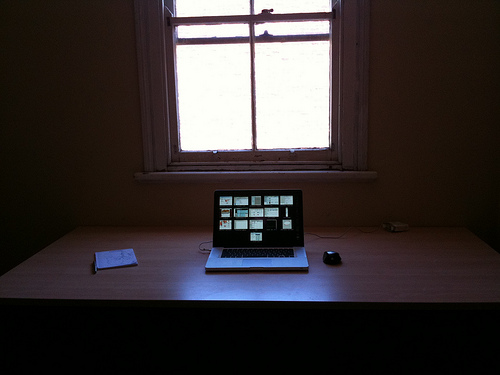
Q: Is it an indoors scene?
A: Yes, it is indoors.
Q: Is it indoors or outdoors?
A: It is indoors.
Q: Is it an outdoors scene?
A: No, it is indoors.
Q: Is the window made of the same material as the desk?
A: No, the window is made of glass and the desk is made of wood.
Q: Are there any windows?
A: Yes, there is a window.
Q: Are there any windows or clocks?
A: Yes, there is a window.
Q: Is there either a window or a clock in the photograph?
A: Yes, there is a window.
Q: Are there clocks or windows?
A: Yes, there is a window.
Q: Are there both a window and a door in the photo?
A: No, there is a window but no doors.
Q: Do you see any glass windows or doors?
A: Yes, there is a glass window.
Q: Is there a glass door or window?
A: Yes, there is a glass window.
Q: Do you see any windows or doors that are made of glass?
A: Yes, the window is made of glass.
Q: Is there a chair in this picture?
A: No, there are no chairs.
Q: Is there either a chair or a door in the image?
A: No, there are no chairs or doors.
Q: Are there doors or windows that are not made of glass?
A: No, there is a window but it is made of glass.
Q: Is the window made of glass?
A: Yes, the window is made of glass.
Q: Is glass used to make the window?
A: Yes, the window is made of glass.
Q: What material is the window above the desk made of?
A: The window is made of glass.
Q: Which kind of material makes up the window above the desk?
A: The window is made of glass.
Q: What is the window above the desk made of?
A: The window is made of glass.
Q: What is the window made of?
A: The window is made of glass.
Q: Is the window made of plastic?
A: No, the window is made of glass.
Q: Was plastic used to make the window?
A: No, the window is made of glass.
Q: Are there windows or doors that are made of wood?
A: No, there is a window but it is made of glass.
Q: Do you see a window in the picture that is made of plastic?
A: No, there is a window but it is made of glass.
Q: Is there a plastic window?
A: No, there is a window but it is made of glass.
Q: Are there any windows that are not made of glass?
A: No, there is a window but it is made of glass.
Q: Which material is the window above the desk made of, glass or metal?
A: The window is made of glass.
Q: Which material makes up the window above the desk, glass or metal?
A: The window is made of glass.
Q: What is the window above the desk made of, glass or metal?
A: The window is made of glass.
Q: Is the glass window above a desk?
A: Yes, the window is above a desk.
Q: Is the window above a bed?
A: No, the window is above a desk.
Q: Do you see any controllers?
A: No, there are no controllers.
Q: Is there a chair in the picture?
A: No, there are no chairs.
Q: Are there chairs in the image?
A: No, there are no chairs.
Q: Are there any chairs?
A: No, there are no chairs.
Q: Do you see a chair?
A: No, there are no chairs.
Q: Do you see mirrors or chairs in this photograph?
A: No, there are no chairs or mirrors.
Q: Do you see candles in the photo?
A: No, there are no candles.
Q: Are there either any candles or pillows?
A: No, there are no candles or pillows.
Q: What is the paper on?
A: The paper is on the desk.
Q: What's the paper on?
A: The paper is on the desk.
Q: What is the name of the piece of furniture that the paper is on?
A: The piece of furniture is a desk.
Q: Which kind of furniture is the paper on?
A: The paper is on the desk.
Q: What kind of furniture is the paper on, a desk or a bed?
A: The paper is on a desk.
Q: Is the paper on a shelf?
A: No, the paper is on a desk.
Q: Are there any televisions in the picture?
A: No, there are no televisions.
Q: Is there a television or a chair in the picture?
A: No, there are no televisions or chairs.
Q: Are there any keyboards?
A: Yes, there is a keyboard.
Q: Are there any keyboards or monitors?
A: Yes, there is a keyboard.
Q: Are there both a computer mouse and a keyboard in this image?
A: Yes, there are both a keyboard and a computer mouse.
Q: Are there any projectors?
A: No, there are no projectors.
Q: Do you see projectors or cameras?
A: No, there are no projectors or cameras.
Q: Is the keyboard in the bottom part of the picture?
A: Yes, the keyboard is in the bottom of the image.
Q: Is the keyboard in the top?
A: No, the keyboard is in the bottom of the image.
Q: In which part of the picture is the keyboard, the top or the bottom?
A: The keyboard is in the bottom of the image.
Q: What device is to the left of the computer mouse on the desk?
A: The device is a keyboard.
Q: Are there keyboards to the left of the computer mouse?
A: Yes, there is a keyboard to the left of the computer mouse.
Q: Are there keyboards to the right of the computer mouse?
A: No, the keyboard is to the left of the computer mouse.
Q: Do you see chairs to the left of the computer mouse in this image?
A: No, there is a keyboard to the left of the computer mouse.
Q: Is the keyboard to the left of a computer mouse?
A: Yes, the keyboard is to the left of a computer mouse.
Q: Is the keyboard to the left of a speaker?
A: No, the keyboard is to the left of a computer mouse.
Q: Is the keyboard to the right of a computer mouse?
A: No, the keyboard is to the left of a computer mouse.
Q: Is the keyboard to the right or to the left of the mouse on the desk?
A: The keyboard is to the left of the mouse.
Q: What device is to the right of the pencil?
A: The device is a keyboard.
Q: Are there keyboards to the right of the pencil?
A: Yes, there is a keyboard to the right of the pencil.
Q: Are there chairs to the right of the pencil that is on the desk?
A: No, there is a keyboard to the right of the pencil.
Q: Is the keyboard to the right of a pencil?
A: Yes, the keyboard is to the right of a pencil.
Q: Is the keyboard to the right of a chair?
A: No, the keyboard is to the right of a pencil.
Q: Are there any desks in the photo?
A: Yes, there is a desk.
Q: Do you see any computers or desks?
A: Yes, there is a desk.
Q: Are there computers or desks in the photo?
A: Yes, there is a desk.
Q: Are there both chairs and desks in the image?
A: No, there is a desk but no chairs.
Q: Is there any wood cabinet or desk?
A: Yes, there is a wood desk.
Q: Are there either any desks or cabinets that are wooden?
A: Yes, the desk is wooden.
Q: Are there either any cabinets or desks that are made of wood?
A: Yes, the desk is made of wood.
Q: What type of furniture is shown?
A: The furniture is a desk.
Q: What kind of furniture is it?
A: The piece of furniture is a desk.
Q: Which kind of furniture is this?
A: This is a desk.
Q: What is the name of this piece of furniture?
A: This is a desk.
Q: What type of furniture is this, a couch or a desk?
A: This is a desk.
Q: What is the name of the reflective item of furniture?
A: The piece of furniture is a desk.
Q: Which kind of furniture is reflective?
A: The furniture is a desk.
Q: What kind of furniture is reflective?
A: The furniture is a desk.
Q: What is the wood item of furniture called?
A: The piece of furniture is a desk.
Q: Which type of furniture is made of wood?
A: The furniture is a desk.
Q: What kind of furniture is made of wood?
A: The furniture is a desk.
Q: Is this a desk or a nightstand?
A: This is a desk.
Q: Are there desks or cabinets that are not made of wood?
A: No, there is a desk but it is made of wood.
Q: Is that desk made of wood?
A: Yes, the desk is made of wood.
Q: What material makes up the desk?
A: The desk is made of wood.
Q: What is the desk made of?
A: The desk is made of wood.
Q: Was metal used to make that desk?
A: No, the desk is made of wood.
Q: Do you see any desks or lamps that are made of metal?
A: No, there is a desk but it is made of wood.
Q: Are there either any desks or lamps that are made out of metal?
A: No, there is a desk but it is made of wood.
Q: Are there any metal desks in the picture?
A: No, there is a desk but it is made of wood.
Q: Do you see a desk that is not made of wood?
A: No, there is a desk but it is made of wood.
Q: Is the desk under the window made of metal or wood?
A: The desk is made of wood.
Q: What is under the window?
A: The desk is under the window.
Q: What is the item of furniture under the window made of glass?
A: The piece of furniture is a desk.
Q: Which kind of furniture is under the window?
A: The piece of furniture is a desk.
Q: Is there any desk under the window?
A: Yes, there is a desk under the window.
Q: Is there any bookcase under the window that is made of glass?
A: No, there is a desk under the window.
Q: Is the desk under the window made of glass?
A: Yes, the desk is under the window.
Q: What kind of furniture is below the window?
A: The piece of furniture is a desk.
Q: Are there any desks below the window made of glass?
A: Yes, there is a desk below the window.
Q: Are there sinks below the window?
A: No, there is a desk below the window.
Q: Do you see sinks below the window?
A: No, there is a desk below the window.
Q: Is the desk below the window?
A: Yes, the desk is below the window.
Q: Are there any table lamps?
A: No, there are no table lamps.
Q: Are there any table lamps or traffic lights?
A: No, there are no table lamps or traffic lights.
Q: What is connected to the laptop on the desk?
A: The cable is connected to the laptop.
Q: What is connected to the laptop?
A: The cable is connected to the laptop.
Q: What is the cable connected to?
A: The cable is connected to the laptop.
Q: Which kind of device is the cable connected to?
A: The cable is connected to the laptop.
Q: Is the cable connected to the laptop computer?
A: Yes, the cable is connected to the laptop computer.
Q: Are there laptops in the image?
A: Yes, there is a laptop.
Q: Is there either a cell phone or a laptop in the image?
A: Yes, there is a laptop.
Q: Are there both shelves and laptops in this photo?
A: No, there is a laptop but no shelves.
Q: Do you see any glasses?
A: No, there are no glasses.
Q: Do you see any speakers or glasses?
A: No, there are no glasses or speakers.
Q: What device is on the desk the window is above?
A: The device is a laptop.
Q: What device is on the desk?
A: The device is a laptop.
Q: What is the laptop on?
A: The laptop is on the desk.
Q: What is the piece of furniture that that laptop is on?
A: The piece of furniture is a desk.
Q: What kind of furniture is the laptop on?
A: The laptop is on the desk.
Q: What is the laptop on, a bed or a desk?
A: The laptop is on a desk.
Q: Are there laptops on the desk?
A: Yes, there is a laptop on the desk.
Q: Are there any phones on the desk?
A: No, there is a laptop on the desk.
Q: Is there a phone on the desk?
A: No, there is a laptop on the desk.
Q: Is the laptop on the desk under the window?
A: Yes, the laptop is on the desk.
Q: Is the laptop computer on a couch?
A: No, the laptop computer is on the desk.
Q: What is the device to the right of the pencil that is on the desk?
A: The device is a laptop.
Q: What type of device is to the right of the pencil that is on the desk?
A: The device is a laptop.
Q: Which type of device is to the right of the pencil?
A: The device is a laptop.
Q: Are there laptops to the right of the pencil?
A: Yes, there is a laptop to the right of the pencil.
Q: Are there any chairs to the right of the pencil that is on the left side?
A: No, there is a laptop to the right of the pencil.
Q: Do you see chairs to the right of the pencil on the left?
A: No, there is a laptop to the right of the pencil.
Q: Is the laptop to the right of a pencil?
A: Yes, the laptop is to the right of a pencil.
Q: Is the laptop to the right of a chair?
A: No, the laptop is to the right of a pencil.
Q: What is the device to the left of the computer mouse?
A: The device is a laptop.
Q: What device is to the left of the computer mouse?
A: The device is a laptop.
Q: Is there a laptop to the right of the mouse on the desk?
A: No, the laptop is to the left of the computer mouse.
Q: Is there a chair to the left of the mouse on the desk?
A: No, there is a laptop to the left of the computer mouse.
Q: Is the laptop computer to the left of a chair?
A: No, the laptop computer is to the left of the computer mouse.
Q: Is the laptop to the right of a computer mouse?
A: No, the laptop is to the left of a computer mouse.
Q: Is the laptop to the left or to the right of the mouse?
A: The laptop is to the left of the mouse.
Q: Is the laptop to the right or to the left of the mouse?
A: The laptop is to the left of the mouse.